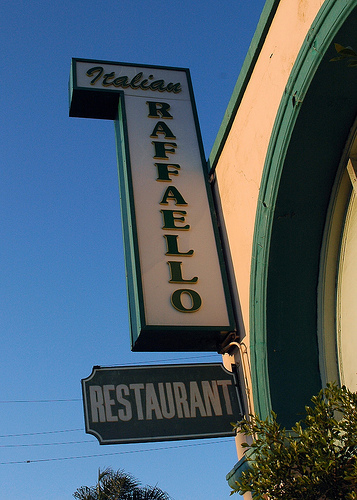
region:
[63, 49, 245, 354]
A sign shaped like a seven.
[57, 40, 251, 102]
Italian is written in cursive lettering.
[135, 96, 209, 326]
Raffaello is written in printed letters.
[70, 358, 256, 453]
A sign that says, "restaurant."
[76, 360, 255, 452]
The sign is green.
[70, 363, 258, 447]
The lettering is white.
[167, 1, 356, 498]
The building is green and tan.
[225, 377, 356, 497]
The tree is next to the building.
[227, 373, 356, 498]
The tree is green and leafy.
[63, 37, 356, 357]
The sign is attached to a building.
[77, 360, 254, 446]
resturant sign on the side of a building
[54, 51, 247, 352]
white sign for a restaurant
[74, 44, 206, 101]
cursive writing on a restaurant sign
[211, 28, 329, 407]
archway of a building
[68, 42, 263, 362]
sign shaped like a seven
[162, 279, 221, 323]
black letter O on a sign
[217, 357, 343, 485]
green bush in front of a restaurant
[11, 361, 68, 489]
power lines strung through the air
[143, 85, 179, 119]
letter r on a sign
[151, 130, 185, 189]
double letter f on a sign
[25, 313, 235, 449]
restaurant sign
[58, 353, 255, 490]
restaurant sign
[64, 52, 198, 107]
green and white Italian sign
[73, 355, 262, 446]
green and white restaurant sign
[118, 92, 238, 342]
green and white sign that says Raffaello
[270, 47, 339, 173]
large wooden painted door trim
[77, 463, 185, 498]
leaves of a tropical tree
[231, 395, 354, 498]
bush near a windows still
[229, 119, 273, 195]
peach painted exterior wall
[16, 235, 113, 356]
sky that is clear of clouds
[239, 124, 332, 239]
thick exterior painted wall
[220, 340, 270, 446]
painted electric metal pole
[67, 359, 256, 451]
A sign advertising a restaurant.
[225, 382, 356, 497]
The tree is green.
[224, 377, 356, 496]
The tree is leafy.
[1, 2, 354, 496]
The sky is blue.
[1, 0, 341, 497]
The sky is clear.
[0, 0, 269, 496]
The sky is cloudless.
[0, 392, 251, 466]
Electric wires in the background.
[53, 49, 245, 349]
The sign is green.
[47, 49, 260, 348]
The sign is white.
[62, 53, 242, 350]
Sign advertising Italian food.